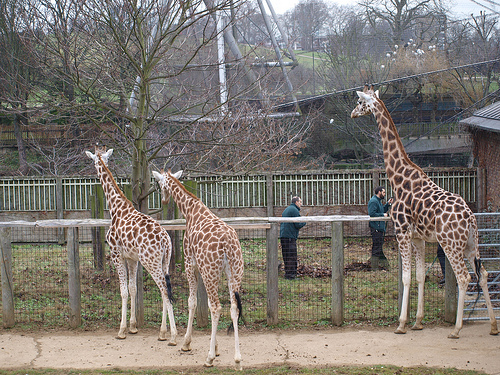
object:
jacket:
[277, 205, 306, 240]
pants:
[279, 238, 297, 281]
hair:
[373, 186, 383, 195]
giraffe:
[348, 85, 499, 338]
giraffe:
[83, 144, 178, 346]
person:
[278, 195, 307, 280]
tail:
[223, 242, 248, 326]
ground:
[0, 234, 498, 374]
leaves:
[303, 262, 327, 276]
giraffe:
[150, 169, 245, 372]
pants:
[368, 228, 389, 259]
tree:
[305, 10, 441, 204]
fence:
[0, 210, 499, 331]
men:
[366, 185, 394, 261]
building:
[458, 96, 500, 256]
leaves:
[260, 148, 294, 172]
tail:
[464, 211, 482, 301]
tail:
[161, 235, 175, 303]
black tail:
[469, 216, 481, 299]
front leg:
[391, 212, 412, 334]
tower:
[121, 0, 303, 124]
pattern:
[432, 216, 444, 233]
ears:
[354, 89, 368, 97]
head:
[348, 85, 381, 119]